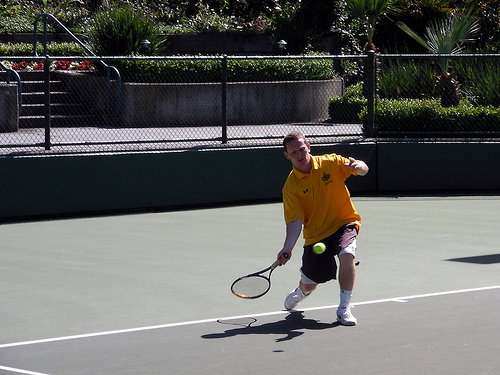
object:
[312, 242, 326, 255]
ball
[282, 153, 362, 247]
shirt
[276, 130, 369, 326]
man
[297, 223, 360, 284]
shorts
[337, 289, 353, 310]
sock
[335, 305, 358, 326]
shoe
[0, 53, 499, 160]
fence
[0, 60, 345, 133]
wall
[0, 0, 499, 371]
ground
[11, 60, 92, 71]
flowers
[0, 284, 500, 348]
line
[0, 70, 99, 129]
stair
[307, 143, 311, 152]
ear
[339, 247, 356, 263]
knee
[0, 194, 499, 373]
tennis court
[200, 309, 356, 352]
shadow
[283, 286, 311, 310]
shoe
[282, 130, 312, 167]
head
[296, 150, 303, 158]
nose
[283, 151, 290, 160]
ear